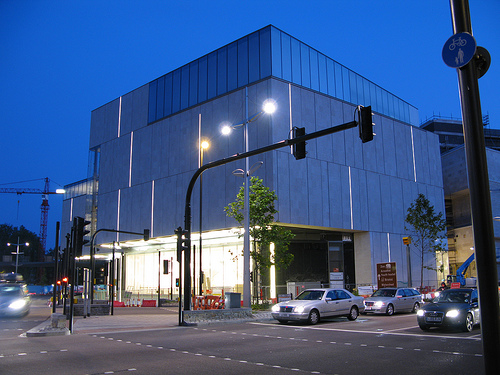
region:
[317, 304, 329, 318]
part of a wheel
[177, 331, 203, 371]
aprt of a loine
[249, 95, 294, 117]
this is a light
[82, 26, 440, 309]
this is a building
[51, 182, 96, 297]
this is a building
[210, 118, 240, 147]
this is a light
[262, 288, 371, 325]
this is a car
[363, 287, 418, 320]
this is a car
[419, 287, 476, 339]
this is a car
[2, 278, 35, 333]
this is a car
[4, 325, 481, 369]
this is a road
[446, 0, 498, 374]
this is a pole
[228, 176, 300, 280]
tree with green leaves behind pole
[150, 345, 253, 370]
white lines painted on pavement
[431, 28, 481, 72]
blue metal sign on black pole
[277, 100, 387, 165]
black metal traffic signals above road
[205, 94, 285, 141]
silver metal street lights beside road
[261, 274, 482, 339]
cars stopped at traffic signal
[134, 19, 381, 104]
row of windows on side of building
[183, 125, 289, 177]
black metal traffic signal pole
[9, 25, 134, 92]
clear blue evening sky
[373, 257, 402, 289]
large red sign outside building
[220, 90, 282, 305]
a lamp post is on the street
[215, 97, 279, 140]
the lights on the lampost are on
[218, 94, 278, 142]
the lights are white in color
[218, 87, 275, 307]
the lampost is made of metal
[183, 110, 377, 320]
the traffic light is made of metal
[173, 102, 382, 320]
the traffic light pole is black in color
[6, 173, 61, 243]
a crane is in the distance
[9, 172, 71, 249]
the crane is made of metal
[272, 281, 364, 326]
the car is grey in color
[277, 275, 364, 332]
a car on a street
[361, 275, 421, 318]
a car on a street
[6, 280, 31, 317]
a car on a street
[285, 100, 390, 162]
Back of two traffic lights hanging over the street.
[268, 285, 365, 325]
First silver car at the light.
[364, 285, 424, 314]
Second silver car at the light.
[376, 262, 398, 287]
Brown sign behind the second silver car.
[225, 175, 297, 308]
Tree closest to the first car.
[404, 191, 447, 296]
Tree farthest from the traffic light.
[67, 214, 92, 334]
Closest single traffic light on a metal pole.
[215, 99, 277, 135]
Two white lights above the cars.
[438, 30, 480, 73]
Blue circle sign with people and bikes.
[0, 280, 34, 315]
Blurry car to the far left.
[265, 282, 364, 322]
The silver car is driving down the street.